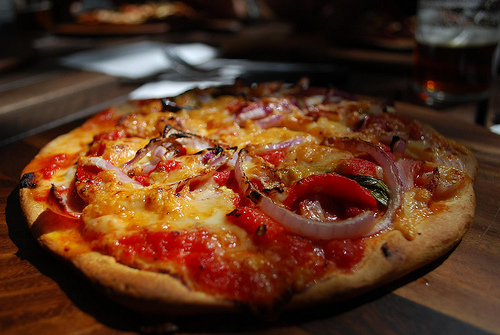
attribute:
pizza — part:
[19, 112, 485, 308]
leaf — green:
[343, 167, 389, 209]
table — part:
[1, 73, 498, 332]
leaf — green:
[358, 165, 393, 208]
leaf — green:
[339, 170, 391, 210]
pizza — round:
[14, 64, 478, 315]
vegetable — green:
[353, 175, 394, 206]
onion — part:
[234, 138, 402, 239]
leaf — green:
[345, 145, 412, 221]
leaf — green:
[342, 172, 393, 202]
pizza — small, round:
[18, 83, 480, 309]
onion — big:
[237, 132, 404, 236]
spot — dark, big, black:
[19, 170, 44, 190]